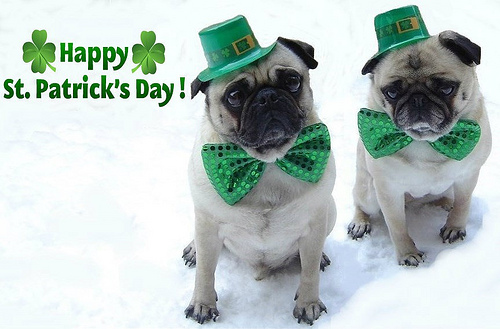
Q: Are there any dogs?
A: Yes, there is a dog.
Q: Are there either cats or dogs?
A: Yes, there is a dog.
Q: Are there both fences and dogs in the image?
A: No, there is a dog but no fences.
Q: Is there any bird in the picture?
A: No, there are no birds.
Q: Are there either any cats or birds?
A: No, there are no birds or cats.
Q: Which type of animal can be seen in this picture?
A: The animal is a dog.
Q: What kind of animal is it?
A: The animal is a dog.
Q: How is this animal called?
A: This is a dog.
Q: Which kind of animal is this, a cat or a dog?
A: This is a dog.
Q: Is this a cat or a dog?
A: This is a dog.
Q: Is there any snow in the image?
A: Yes, there is snow.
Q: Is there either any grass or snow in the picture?
A: Yes, there is snow.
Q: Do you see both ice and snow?
A: No, there is snow but no ice.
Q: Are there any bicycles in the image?
A: No, there are no bicycles.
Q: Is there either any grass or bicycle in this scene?
A: No, there are no bicycles or grass.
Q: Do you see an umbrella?
A: No, there are no umbrellas.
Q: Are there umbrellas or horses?
A: No, there are no umbrellas or horses.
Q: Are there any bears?
A: No, there are no bears.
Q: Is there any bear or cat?
A: No, there are no bears or cats.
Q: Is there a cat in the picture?
A: No, there are no cats.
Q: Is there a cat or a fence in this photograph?
A: No, there are no cats or fences.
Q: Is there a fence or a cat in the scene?
A: No, there are no cats or fences.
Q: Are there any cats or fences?
A: No, there are no cats or fences.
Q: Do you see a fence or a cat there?
A: No, there are no cats or fences.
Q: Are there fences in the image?
A: No, there are no fences.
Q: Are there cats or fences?
A: No, there are no fences or cats.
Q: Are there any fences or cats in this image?
A: No, there are no fences or cats.